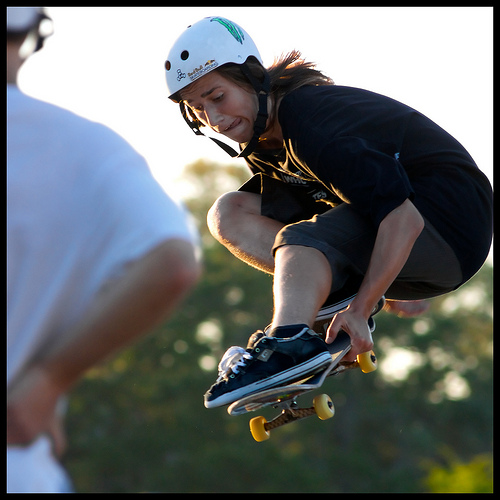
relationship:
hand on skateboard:
[324, 298, 391, 363] [174, 306, 434, 493]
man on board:
[162, 10, 494, 408] [210, 319, 384, 429]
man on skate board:
[162, 10, 494, 408] [213, 312, 386, 444]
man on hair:
[162, 10, 494, 408] [226, 51, 332, 89]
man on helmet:
[162, 10, 494, 408] [158, 14, 268, 104]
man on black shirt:
[162, 10, 494, 408] [235, 77, 493, 291]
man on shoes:
[162, 10, 494, 408] [189, 316, 331, 406]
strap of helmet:
[181, 65, 272, 156] [163, 15, 265, 99]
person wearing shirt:
[0, 5, 218, 495] [8, 82, 195, 499]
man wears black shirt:
[162, 10, 494, 408] [235, 77, 493, 291]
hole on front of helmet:
[163, 61, 171, 71] [164, 16, 270, 162]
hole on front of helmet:
[178, 50, 187, 60] [164, 16, 270, 162]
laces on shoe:
[216, 345, 254, 377] [199, 324, 346, 406]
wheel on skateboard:
[357, 349, 377, 373] [202, 314, 375, 441]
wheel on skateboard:
[249, 414, 269, 439] [202, 314, 375, 441]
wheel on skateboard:
[312, 391, 334, 418] [202, 314, 375, 441]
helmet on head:
[163, 15, 265, 99] [156, 10, 272, 142]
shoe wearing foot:
[203, 325, 333, 409] [201, 307, 352, 417]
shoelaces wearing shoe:
[211, 336, 253, 371] [203, 303, 353, 414]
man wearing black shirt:
[162, 10, 471, 409] [235, 77, 493, 291]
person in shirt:
[0, 5, 218, 495] [8, 82, 195, 499]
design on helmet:
[212, 19, 249, 44] [163, 15, 265, 99]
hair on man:
[226, 52, 332, 83] [170, 15, 494, 405]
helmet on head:
[130, 15, 285, 122] [173, 25, 308, 147]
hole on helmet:
[180, 50, 189, 61] [163, 15, 265, 99]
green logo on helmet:
[203, 15, 250, 46] [141, 9, 269, 108]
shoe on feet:
[203, 325, 333, 409] [206, 323, 347, 413]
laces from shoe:
[216, 345, 254, 377] [203, 325, 333, 409]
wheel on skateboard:
[312, 391, 334, 418] [201, 331, 381, 445]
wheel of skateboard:
[312, 391, 334, 418] [225, 297, 402, 422]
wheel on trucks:
[312, 391, 334, 418] [249, 350, 393, 462]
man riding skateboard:
[162, 10, 494, 408] [230, 317, 377, 444]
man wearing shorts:
[162, 10, 494, 408] [230, 158, 483, 313]